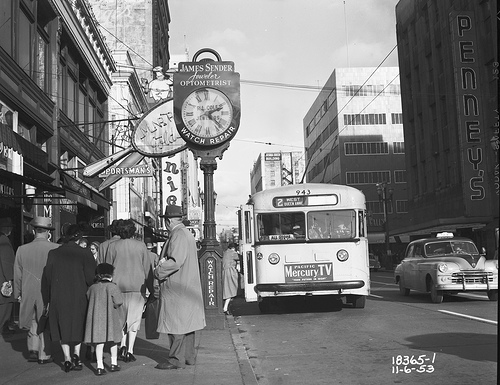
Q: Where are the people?
A: On the sidewalk.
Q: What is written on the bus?
A: Mercury TV.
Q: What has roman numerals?
A: Clock.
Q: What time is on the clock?
A: 2:22.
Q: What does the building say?
A: Penney's.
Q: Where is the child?
A: With the adults.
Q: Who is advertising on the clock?
A: James Sender.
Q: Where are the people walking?
A: City sidewalk.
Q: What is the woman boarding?
A: Bus.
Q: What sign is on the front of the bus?
A: Pacific Mercury TV.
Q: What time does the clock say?
A: 2:23.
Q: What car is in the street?
A: Taxi cab.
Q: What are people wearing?
A: Long coats.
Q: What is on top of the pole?
A: Clock.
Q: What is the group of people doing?
A: Walking down the street.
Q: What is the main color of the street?
A: Gray.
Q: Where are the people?
A: On the sidewalk.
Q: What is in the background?
A: Buildings.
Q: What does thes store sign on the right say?
A: Penney's.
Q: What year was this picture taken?
A: 1953.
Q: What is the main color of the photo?
A: Black and white.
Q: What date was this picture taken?
A: November 1953.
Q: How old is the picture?
A: Very old.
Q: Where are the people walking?
A: At the sidewalk.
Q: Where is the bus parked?
A: Beside the sidewalk.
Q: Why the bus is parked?
A: To load passengers.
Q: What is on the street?
A: Cab and bus.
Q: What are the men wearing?
A: Hat and coat.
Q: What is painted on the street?
A: White line.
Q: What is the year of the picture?
A: 1953.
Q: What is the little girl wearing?
A: A coat, hat and shoes.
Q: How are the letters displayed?
A: Vertically.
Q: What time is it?
A: It is 2:20.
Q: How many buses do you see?
A: 1.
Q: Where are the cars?
A: On the street.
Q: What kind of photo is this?
A: Black and white.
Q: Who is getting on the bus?
A: A woman.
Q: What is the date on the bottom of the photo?
A: 11-6-53.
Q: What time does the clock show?
A: 2:23.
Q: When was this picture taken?
A: 1953.